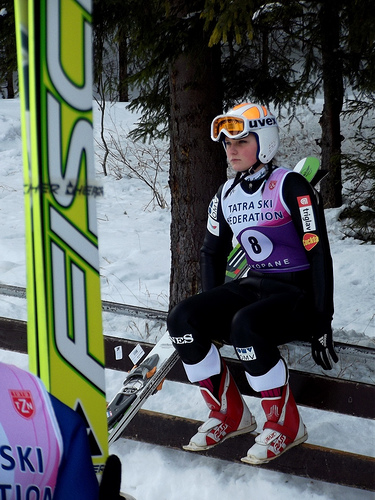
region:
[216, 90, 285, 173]
woman wears white helmet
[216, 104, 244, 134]
woman wears orange goggles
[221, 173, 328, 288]
woman wears multicolor top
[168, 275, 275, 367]
woman wears black pants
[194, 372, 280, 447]
woman wears red shoes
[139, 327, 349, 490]
woman sits on ledge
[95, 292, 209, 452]
woman has white skis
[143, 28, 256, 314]
tree behind woman is brown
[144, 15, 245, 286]
tree behind woman has thick trunk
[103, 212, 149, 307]
snow on ground next to tree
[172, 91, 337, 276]
girl in a snow suit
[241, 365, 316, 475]
red and white shoes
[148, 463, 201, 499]
snow on the ground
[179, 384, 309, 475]
two feet of person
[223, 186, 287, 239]
words on the gear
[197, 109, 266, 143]
goggles on person's head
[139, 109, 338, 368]
girl sitting on fence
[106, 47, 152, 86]
tree in the background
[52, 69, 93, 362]
white letters on board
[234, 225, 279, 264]
the number eight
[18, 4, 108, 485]
Set of skis in the foreground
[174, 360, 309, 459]
Boots used for skiing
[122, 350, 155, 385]
Binding used for skiing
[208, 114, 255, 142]
Orange goggles for eye protection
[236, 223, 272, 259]
Number of competitor on ski suit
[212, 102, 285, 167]
Helmet worn for head protection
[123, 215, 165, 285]
Snow on the ground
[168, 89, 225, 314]
Trunk of the tree in the background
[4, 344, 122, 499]
Another snow skier in the foreground of view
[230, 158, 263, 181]
Strap to keep helmet secure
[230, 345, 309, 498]
a red and white boots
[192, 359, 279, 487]
a red and white boots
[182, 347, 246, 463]
a red and white boots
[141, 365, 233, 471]
a red and white boots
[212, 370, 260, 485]
a red and white boots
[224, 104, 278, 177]
girl has white helmet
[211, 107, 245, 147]
girl has orange goggles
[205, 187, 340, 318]
girl has multi-colored shirt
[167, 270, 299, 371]
girl has black pants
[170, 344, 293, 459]
girl has red shoes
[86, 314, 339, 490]
girl sits on brown fence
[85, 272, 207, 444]
girl wears white skis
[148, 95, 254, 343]
brown thick tree behind girl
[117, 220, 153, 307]
white snow beside tree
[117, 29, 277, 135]
pine tree behind girl